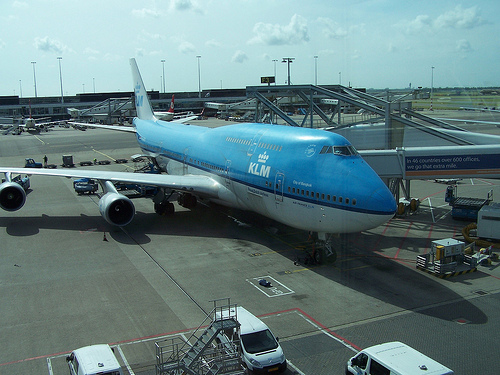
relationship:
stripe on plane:
[135, 140, 400, 217] [1, 57, 406, 266]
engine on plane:
[0, 173, 27, 210] [1, 57, 406, 266]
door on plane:
[273, 168, 285, 204] [5, 55, 497, 254]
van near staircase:
[212, 306, 283, 370] [155, 300, 242, 372]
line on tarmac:
[280, 252, 370, 274] [1, 109, 498, 374]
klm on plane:
[231, 160, 278, 179] [1, 62, 432, 244]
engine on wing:
[80, 182, 161, 245] [1, 160, 225, 227]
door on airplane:
[273, 168, 285, 204] [119, 55, 398, 256]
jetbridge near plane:
[351, 141, 485, 183] [5, 55, 497, 254]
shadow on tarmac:
[0, 214, 487, 329] [3, 132, 493, 373]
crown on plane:
[256, 150, 269, 164] [1, 57, 406, 266]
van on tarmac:
[63, 342, 128, 373] [0, 136, 496, 348]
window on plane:
[353, 198, 358, 206] [1, 57, 406, 266]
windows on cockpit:
[320, 142, 361, 157] [318, 141, 362, 160]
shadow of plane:
[1, 195, 499, 324] [1, 57, 406, 266]